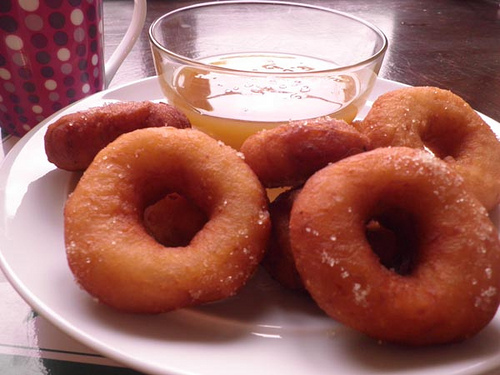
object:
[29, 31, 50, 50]
polka dot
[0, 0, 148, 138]
coffee cup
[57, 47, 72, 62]
polka dot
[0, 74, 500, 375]
plate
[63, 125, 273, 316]
donut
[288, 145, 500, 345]
donut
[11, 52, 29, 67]
polka dot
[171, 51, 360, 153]
sauce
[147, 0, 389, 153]
bowl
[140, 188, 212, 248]
hole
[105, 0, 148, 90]
handle